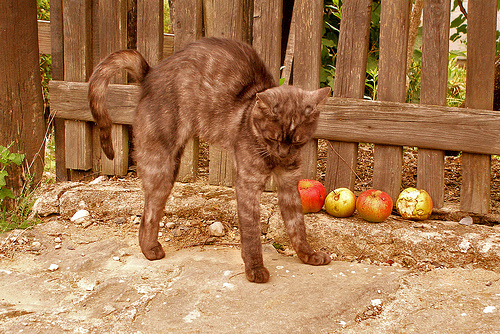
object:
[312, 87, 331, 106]
ear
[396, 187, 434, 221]
apple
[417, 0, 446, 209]
wooden post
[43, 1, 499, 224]
fence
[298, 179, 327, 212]
apple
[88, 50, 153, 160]
tail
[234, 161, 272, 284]
legs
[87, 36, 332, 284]
cat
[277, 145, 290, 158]
nose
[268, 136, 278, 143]
eyes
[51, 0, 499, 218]
wall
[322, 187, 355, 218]
apple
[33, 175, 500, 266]
ledge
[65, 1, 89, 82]
back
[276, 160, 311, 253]
legs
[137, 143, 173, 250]
legs